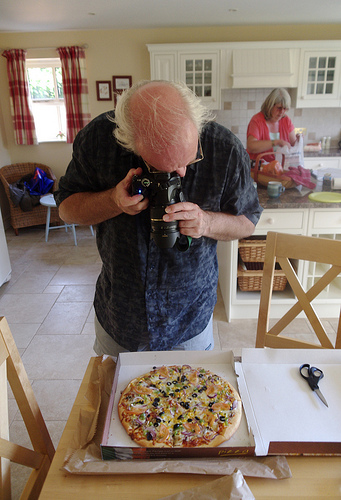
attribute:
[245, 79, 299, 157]
woman — unpacking, old, grey, bigger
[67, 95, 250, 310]
man — bald, white, grey, watching, looking, snapping, balding, old, older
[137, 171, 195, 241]
camera — black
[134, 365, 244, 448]
pizza — yellow, full, hot, ready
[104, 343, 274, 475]
box — white, close, small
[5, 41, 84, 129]
curtains — checkered